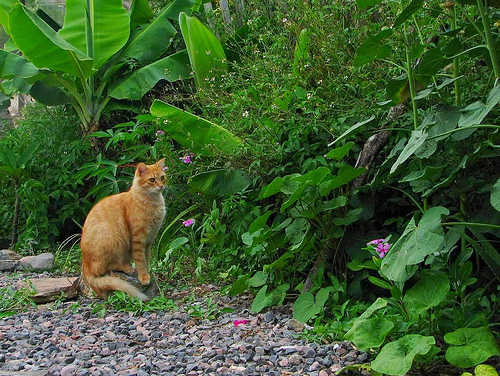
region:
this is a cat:
[79, 153, 176, 288]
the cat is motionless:
[81, 155, 173, 300]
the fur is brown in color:
[103, 200, 131, 245]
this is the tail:
[98, 276, 141, 300]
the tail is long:
[94, 277, 140, 294]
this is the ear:
[138, 162, 148, 169]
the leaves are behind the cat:
[27, 6, 110, 64]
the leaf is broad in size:
[86, 10, 124, 46]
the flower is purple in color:
[373, 235, 394, 252]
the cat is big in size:
[79, 194, 124, 280]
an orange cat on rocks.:
[67, 153, 172, 305]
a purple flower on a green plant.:
[359, 228, 395, 268]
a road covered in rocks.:
[0, 251, 460, 370]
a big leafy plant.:
[146, 96, 248, 159]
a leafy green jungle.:
[11, 0, 497, 370]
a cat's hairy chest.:
[141, 197, 165, 224]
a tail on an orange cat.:
[72, 274, 154, 307]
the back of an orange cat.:
[77, 196, 126, 251]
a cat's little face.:
[144, 171, 166, 191]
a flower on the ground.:
[212, 307, 266, 337]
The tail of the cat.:
[95, 272, 153, 304]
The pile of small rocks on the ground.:
[10, 297, 357, 374]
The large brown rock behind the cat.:
[18, 269, 76, 296]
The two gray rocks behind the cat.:
[3, 242, 55, 269]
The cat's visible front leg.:
[135, 236, 147, 275]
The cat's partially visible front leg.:
[146, 237, 155, 278]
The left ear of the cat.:
[137, 165, 145, 174]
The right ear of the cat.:
[154, 154, 167, 167]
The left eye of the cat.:
[145, 175, 156, 181]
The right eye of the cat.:
[156, 172, 168, 180]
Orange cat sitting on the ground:
[79, 151, 199, 315]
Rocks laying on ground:
[80, 305, 349, 372]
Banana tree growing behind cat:
[2, 6, 299, 150]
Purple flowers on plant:
[354, 236, 440, 319]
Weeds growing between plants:
[232, 35, 363, 142]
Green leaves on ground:
[247, 259, 404, 355]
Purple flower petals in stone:
[229, 306, 266, 342]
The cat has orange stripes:
[68, 166, 178, 288]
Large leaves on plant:
[95, 32, 247, 164]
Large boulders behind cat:
[4, 243, 86, 314]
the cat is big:
[77, 156, 169, 296]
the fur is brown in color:
[111, 202, 133, 217]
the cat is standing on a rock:
[76, 154, 174, 293]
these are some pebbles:
[45, 302, 212, 369]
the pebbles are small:
[48, 331, 205, 356]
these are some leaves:
[13, 2, 237, 121]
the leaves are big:
[11, 0, 191, 94]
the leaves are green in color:
[217, 55, 420, 102]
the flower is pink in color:
[373, 240, 390, 256]